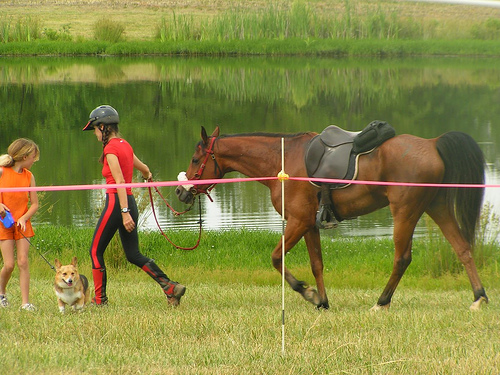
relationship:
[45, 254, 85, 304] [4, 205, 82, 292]
dog on leash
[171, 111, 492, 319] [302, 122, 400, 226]
horse wearing saddle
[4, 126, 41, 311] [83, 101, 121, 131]
girl wearing helmet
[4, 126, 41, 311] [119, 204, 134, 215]
girl wearing watch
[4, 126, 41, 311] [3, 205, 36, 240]
girl wearing shorts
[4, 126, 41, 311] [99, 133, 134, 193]
girl wearing shirt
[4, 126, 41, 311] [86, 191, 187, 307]
girl wearing pants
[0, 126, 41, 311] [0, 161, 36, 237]
girl wearing outfit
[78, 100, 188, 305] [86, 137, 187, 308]
girl wearing outfit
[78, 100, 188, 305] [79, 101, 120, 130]
girl wearing helmet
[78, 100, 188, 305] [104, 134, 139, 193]
girl wearing top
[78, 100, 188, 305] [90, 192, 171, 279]
girl wearing pants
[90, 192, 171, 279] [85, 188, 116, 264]
pants with a stripe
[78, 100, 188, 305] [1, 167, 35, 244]
girl wearing a jumper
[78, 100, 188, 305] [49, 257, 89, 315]
girl walking a dog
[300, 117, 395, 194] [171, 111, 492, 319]
harness on a horse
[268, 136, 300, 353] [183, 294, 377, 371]
white stick stuck in grass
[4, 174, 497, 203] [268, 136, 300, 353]
pink rope attached to a white stick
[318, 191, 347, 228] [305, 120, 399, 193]
brown stirrup attached to a saddle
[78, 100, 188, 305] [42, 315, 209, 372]
girl walking on grass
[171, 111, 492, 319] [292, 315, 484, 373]
horse walking on grass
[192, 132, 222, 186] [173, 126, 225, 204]
rope on horse's face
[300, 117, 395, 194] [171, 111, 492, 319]
harness on horse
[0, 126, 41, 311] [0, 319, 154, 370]
girl standing on grass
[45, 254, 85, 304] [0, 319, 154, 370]
dog standing on grass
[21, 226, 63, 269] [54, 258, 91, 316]
leash on dog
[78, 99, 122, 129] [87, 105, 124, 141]
helmet on woman's head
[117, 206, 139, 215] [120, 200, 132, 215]
watch on woman's wrist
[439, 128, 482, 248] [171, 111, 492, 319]
thick tail of horse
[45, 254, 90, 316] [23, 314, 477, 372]
dog playing in field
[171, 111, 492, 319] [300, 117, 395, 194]
horse with a harness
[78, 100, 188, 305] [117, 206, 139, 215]
girl wearing a watch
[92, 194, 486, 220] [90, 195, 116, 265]
black pants with red stripe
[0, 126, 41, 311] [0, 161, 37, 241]
girl in outfit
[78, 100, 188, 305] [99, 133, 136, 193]
girl wearing a shirt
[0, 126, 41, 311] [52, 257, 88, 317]
girl walking a dog